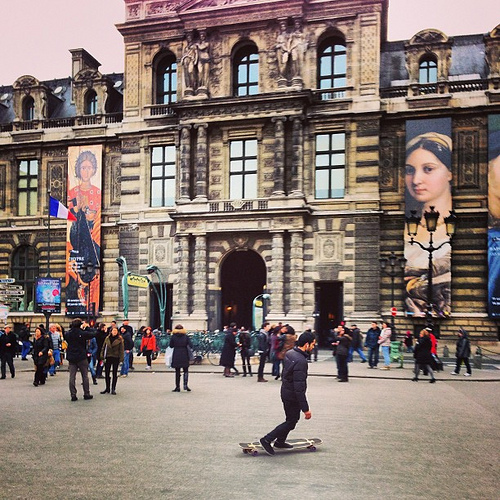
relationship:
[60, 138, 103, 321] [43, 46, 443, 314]
painting on building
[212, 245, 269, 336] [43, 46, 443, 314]
doorway for building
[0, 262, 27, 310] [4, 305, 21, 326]
signs on pst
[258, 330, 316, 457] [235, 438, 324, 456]
man riding skateboard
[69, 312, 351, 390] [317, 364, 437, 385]
people on sidewalk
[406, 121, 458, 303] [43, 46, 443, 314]
artwork on building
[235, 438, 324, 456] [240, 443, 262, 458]
skateboard has wheels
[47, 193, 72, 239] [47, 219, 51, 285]
flag on pole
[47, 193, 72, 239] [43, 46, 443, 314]
flag by building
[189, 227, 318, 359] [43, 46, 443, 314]
doorway of building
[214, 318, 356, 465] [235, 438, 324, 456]
man on skateboard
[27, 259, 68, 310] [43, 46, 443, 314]
art on building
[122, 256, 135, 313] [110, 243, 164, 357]
green tall lamp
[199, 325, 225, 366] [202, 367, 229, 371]
bike on curb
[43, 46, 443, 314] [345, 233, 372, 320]
building of stone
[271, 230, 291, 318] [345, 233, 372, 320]
column made of stone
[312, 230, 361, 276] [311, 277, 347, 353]
decoration above doorway